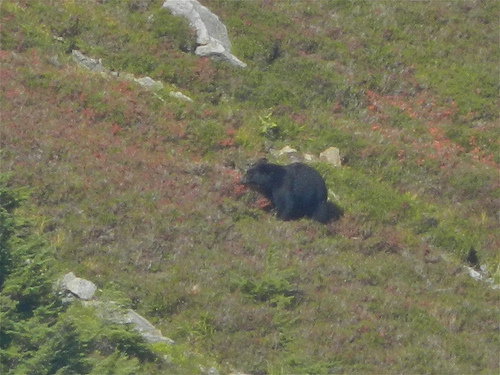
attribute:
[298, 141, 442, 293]
plant — green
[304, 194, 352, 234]
leg — hind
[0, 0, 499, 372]
field — green, grassy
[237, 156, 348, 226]
animal — black, small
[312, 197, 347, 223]
tail — furry, black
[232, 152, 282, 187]
head — small, black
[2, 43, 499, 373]
grass — dry, brownish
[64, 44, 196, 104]
rocks — gray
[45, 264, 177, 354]
rock — large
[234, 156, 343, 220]
animal — black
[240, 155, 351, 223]
bear — black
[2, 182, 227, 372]
bushes — green and brown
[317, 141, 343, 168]
rock — gray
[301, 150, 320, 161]
rock — gray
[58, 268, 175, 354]
rock — gray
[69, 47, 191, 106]
rock — gray, large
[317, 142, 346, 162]
rock — gray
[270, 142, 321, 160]
rock — gray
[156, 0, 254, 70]
rock — large, gray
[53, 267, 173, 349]
rock — gray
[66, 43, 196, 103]
rock — gray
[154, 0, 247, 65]
rock — gray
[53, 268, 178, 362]
rock — gray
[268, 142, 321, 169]
rock — gray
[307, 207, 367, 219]
leg — black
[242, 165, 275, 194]
head — black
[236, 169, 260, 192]
mouth — black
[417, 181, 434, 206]
plant — green